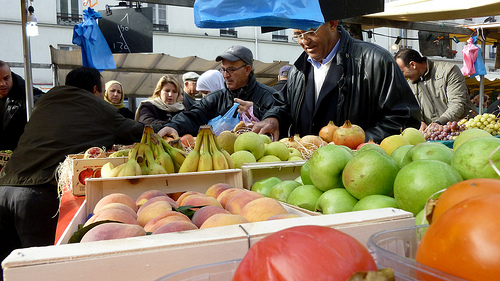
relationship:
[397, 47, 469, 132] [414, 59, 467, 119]
man wearing a jacket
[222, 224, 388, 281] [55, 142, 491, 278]
persimmons at front of table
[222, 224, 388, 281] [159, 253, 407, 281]
persimmons stored inside box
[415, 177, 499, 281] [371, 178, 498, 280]
tomatoes stored inside box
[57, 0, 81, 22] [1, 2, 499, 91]
windows are on side of a building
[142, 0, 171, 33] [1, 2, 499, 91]
windows are on side of a building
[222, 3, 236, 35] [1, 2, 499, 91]
windows are on side of a building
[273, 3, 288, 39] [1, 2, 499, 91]
windows are on side of a building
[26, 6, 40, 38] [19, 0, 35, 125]
light bulb hanging from a pole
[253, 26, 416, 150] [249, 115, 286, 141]
man reaching with h hand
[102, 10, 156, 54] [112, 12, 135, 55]
sign lists prices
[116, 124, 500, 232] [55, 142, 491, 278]
fruits displayed on top table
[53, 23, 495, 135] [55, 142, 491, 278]
people are standing behind table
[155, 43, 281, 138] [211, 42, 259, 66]
man wearing a hat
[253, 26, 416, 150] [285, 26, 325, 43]
man wearing glasses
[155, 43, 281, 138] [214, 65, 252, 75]
man wearing glasses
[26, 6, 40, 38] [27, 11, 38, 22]
light bulb socketed in holder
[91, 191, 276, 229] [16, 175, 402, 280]
peaches are inside a box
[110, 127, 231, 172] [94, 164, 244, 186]
bananas are kept in box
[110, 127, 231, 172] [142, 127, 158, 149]
bananas have a stem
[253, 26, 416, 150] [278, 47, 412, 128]
man wearing a jacket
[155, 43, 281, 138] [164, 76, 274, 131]
man wearing a jacket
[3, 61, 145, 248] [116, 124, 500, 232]
man selling fruits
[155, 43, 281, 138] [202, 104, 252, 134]
man buying produce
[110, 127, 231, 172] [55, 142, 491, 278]
bananas are on top of table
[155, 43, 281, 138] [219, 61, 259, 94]
man has a head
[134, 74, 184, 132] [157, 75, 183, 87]
woman has hair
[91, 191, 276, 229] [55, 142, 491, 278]
peaches are on top table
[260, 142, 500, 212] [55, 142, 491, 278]
apples are on top of table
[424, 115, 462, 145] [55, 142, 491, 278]
grapes are on top of table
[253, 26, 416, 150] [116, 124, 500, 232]
man selecting from fruits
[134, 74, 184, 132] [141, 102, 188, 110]
woman wearing a scarf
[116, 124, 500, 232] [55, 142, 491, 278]
fruits are on display on a table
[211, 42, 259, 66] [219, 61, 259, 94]
hat on top of head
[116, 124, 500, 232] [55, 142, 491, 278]
fruits are on top of table